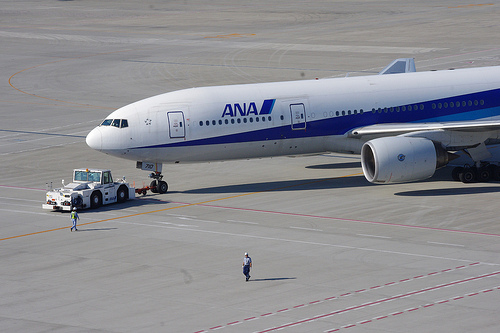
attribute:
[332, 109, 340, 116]
window — small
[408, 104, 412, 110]
window — small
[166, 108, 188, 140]
window — small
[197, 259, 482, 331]
line — white, red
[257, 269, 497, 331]
line — white, red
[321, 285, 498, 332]
line — white, red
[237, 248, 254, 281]
man — walking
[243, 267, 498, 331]
lines — red 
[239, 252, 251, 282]
man — walking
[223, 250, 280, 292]
man — walking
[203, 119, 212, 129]
window — small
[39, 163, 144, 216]
truck — airport guide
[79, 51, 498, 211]
airplane — passenger jet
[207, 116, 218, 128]
window — small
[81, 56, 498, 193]
plane — blue, white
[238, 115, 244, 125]
window — small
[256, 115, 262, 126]
window — small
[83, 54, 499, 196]
airplane — parked